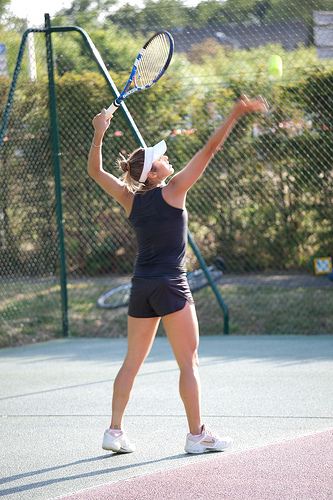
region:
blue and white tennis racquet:
[88, 22, 178, 129]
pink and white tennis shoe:
[184, 431, 237, 467]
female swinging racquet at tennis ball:
[90, 32, 274, 240]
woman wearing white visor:
[111, 123, 197, 195]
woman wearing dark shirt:
[100, 136, 210, 288]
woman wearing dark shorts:
[116, 130, 221, 321]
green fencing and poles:
[8, 33, 97, 355]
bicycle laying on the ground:
[93, 258, 233, 331]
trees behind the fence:
[189, 113, 331, 277]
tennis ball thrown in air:
[207, 35, 298, 128]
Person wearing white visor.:
[134, 138, 177, 197]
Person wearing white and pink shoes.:
[95, 419, 275, 472]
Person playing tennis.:
[73, 420, 233, 484]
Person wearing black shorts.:
[123, 303, 187, 326]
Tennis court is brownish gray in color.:
[176, 470, 241, 493]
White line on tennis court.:
[87, 474, 119, 485]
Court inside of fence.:
[210, 288, 307, 319]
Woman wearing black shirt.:
[120, 217, 172, 252]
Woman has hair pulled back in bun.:
[110, 144, 160, 195]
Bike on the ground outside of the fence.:
[84, 252, 274, 317]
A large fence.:
[12, 19, 101, 330]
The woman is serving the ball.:
[71, 12, 296, 466]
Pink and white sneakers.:
[98, 420, 230, 462]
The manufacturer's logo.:
[194, 428, 218, 450]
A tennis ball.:
[257, 48, 287, 83]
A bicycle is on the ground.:
[184, 253, 228, 301]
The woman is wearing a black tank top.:
[117, 185, 192, 273]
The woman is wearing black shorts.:
[115, 257, 202, 324]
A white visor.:
[116, 136, 172, 187]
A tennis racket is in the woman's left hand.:
[83, 23, 181, 131]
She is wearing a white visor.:
[118, 137, 187, 185]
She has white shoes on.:
[91, 408, 256, 469]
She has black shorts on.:
[110, 260, 224, 337]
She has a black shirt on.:
[106, 156, 204, 293]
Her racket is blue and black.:
[86, 22, 205, 140]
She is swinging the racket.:
[85, 41, 303, 152]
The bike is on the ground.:
[100, 261, 246, 310]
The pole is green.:
[20, 18, 97, 345]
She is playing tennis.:
[93, 114, 257, 476]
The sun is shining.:
[14, 35, 330, 448]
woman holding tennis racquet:
[102, 20, 176, 107]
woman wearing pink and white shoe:
[99, 428, 134, 457]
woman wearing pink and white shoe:
[184, 429, 227, 455]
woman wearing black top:
[125, 191, 186, 276]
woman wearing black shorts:
[133, 274, 192, 312]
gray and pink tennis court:
[48, 455, 319, 491]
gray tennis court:
[230, 338, 299, 431]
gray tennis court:
[23, 353, 100, 471]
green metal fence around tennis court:
[8, 8, 89, 326]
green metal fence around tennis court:
[234, 133, 327, 330]